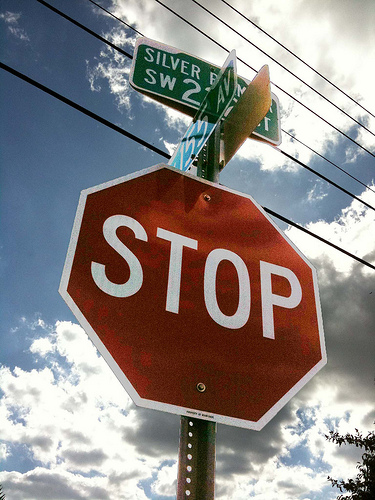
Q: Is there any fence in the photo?
A: No, there are no fences.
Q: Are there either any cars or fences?
A: No, there are no fences or cars.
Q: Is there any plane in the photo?
A: No, there are no airplanes.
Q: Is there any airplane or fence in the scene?
A: No, there are no airplanes or fences.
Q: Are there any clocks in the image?
A: No, there are no clocks.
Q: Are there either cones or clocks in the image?
A: No, there are no clocks or cones.